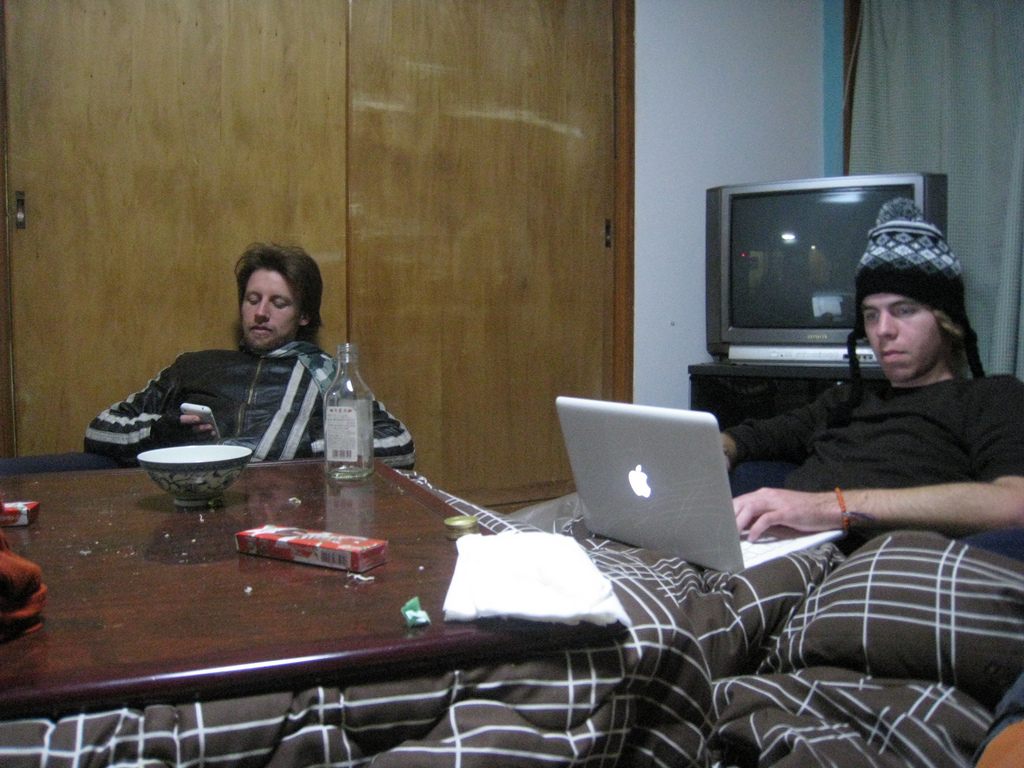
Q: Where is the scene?
A: In a TV room.